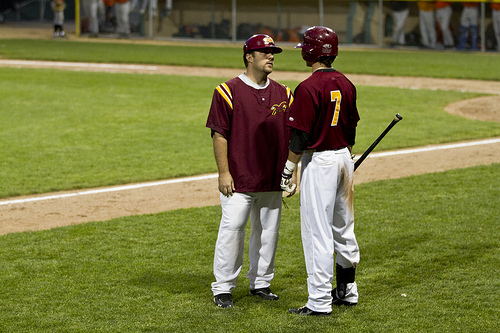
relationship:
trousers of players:
[308, 203, 329, 274] [224, 3, 331, 191]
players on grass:
[224, 3, 331, 191] [105, 50, 115, 54]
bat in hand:
[371, 129, 398, 162] [217, 171, 238, 197]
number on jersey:
[320, 87, 347, 126] [249, 113, 250, 123]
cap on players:
[249, 33, 274, 50] [224, 3, 331, 191]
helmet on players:
[314, 30, 340, 41] [224, 3, 331, 191]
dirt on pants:
[415, 80, 421, 81] [219, 231, 292, 271]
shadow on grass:
[423, 265, 451, 276] [105, 50, 115, 54]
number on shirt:
[320, 87, 347, 126] [319, 79, 327, 83]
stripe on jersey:
[223, 86, 233, 107] [249, 113, 250, 123]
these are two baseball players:
[180, 67, 380, 333] [224, 3, 331, 191]